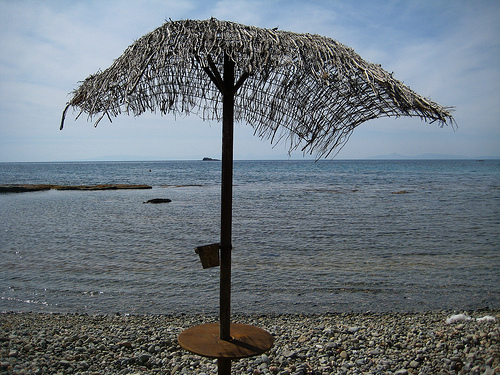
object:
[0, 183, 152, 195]
land protusion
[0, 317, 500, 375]
rock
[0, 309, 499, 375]
beach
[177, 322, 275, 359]
table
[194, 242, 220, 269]
bucket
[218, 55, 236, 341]
pole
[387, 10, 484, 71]
sky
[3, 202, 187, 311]
water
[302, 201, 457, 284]
water